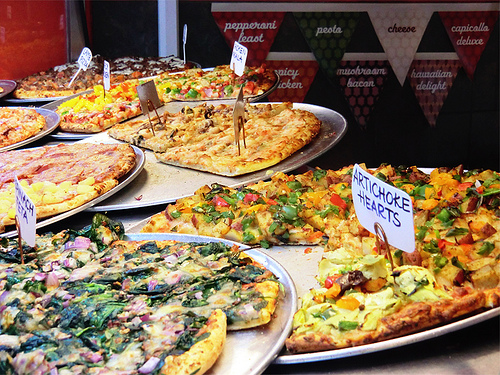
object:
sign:
[352, 163, 415, 271]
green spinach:
[0, 211, 283, 375]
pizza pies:
[0, 55, 500, 375]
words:
[409, 68, 454, 93]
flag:
[365, 10, 434, 86]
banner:
[337, 53, 390, 131]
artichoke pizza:
[143, 163, 499, 353]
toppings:
[0, 177, 116, 224]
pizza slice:
[0, 143, 135, 232]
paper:
[351, 163, 415, 253]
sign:
[233, 83, 247, 156]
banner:
[292, 11, 363, 82]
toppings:
[197, 183, 312, 248]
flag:
[212, 11, 285, 68]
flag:
[297, 11, 363, 78]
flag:
[332, 52, 390, 131]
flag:
[409, 53, 462, 131]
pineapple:
[58, 84, 112, 113]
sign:
[231, 41, 249, 86]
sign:
[15, 176, 37, 264]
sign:
[104, 60, 111, 99]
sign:
[68, 47, 92, 88]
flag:
[437, 10, 500, 82]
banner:
[350, 163, 415, 286]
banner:
[366, 11, 434, 86]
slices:
[108, 102, 320, 178]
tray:
[59, 101, 346, 214]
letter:
[353, 167, 410, 227]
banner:
[212, 12, 286, 67]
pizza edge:
[283, 289, 498, 353]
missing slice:
[148, 233, 325, 357]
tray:
[123, 168, 499, 366]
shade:
[270, 311, 500, 375]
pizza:
[0, 213, 283, 375]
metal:
[373, 222, 394, 272]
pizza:
[107, 101, 322, 177]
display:
[2, 48, 499, 375]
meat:
[31, 70, 91, 86]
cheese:
[12, 49, 194, 100]